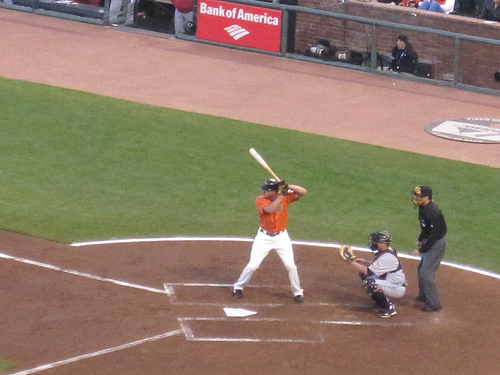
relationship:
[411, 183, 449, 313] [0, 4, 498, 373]
umpire standing on field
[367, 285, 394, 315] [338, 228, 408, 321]
shin guards on catcher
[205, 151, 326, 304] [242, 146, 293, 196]
man about to swing baseball bat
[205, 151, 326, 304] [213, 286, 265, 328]
man at home plate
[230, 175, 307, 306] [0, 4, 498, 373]
man on field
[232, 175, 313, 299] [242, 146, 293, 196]
batter up to baseball bat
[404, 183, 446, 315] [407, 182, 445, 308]
umpire behind catcher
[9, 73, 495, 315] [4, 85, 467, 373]
grass on field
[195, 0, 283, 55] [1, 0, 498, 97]
banner on fence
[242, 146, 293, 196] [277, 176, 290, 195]
baseball bat in batter's hands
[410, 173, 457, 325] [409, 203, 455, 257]
man in shirt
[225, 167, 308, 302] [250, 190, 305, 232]
man in orange shirt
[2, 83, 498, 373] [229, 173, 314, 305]
baseball field with batter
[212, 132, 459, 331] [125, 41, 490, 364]
men playing baseball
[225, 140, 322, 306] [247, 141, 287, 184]
man holding baseball bat